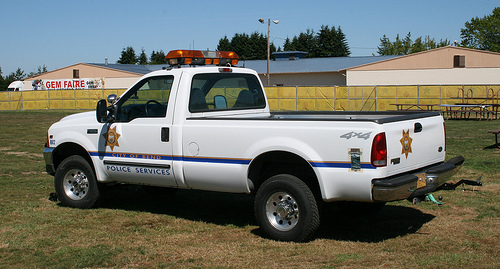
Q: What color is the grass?
A: Green.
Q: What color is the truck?
A: White.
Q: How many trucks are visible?
A: One.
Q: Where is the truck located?
A: On the grass.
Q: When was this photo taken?
A: Outside, during the daytime.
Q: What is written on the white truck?
A: Police Services.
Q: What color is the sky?
A: Blue.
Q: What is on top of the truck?
A: Lights.